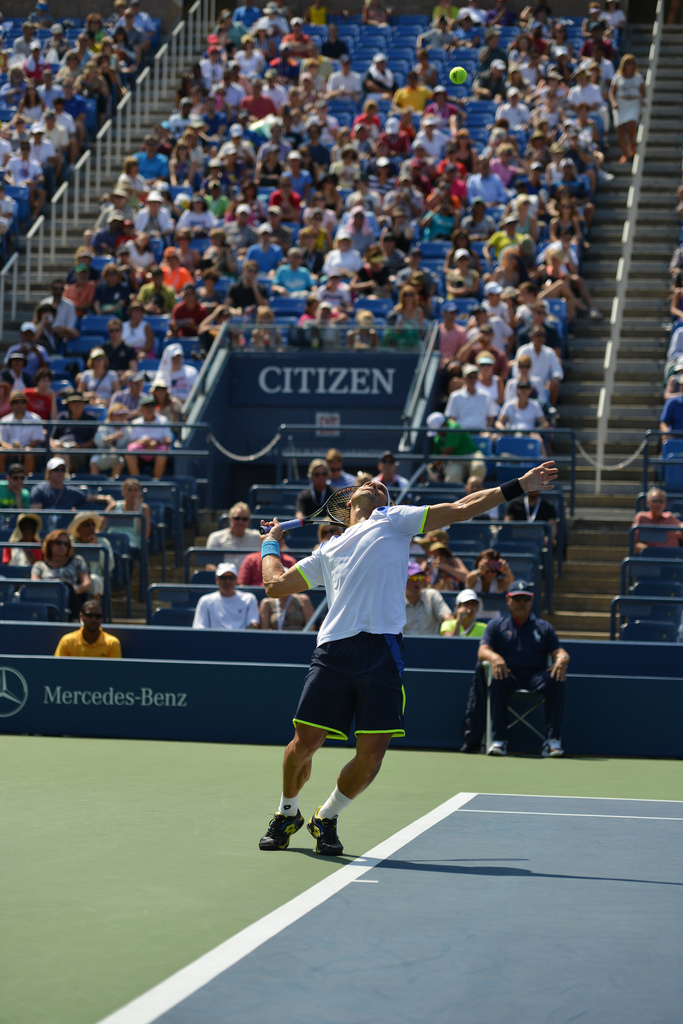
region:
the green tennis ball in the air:
[447, 63, 468, 86]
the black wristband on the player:
[501, 474, 525, 502]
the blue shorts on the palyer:
[294, 631, 412, 741]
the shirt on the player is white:
[296, 504, 432, 644]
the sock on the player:
[278, 792, 300, 818]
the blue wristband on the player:
[260, 538, 282, 558]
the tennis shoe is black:
[258, 807, 304, 852]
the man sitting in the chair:
[473, 576, 573, 755]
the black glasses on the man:
[508, 592, 533, 604]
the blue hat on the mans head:
[507, 577, 535, 597]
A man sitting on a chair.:
[496, 584, 559, 750]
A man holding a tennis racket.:
[263, 473, 402, 560]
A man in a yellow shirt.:
[62, 599, 125, 664]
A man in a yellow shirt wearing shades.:
[64, 593, 118, 666]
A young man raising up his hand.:
[342, 461, 563, 557]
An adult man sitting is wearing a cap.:
[493, 579, 553, 731]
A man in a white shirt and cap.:
[203, 560, 253, 627]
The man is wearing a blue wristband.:
[257, 479, 404, 559]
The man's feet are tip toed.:
[254, 476, 417, 862]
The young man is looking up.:
[331, 472, 408, 573]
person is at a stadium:
[54, 597, 122, 656]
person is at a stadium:
[259, 588, 313, 627]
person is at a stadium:
[477, 578, 574, 758]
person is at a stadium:
[440, 588, 486, 635]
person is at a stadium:
[392, 563, 452, 637]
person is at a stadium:
[465, 551, 512, 590]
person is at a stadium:
[423, 540, 468, 592]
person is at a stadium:
[267, 495, 322, 561]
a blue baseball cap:
[508, 578, 540, 601]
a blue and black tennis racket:
[255, 486, 356, 537]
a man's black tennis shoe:
[306, 809, 343, 853]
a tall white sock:
[316, 789, 356, 818]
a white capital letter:
[257, 363, 284, 398]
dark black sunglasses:
[80, 608, 103, 619]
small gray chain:
[572, 424, 649, 471]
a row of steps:
[554, 3, 675, 524]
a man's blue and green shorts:
[291, 619, 410, 739]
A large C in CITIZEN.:
[256, 362, 280, 396]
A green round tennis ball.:
[448, 66, 467, 85]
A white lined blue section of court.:
[95, 790, 681, 1023]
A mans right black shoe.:
[259, 802, 303, 850]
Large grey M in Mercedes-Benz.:
[43, 684, 63, 705]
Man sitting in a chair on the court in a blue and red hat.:
[477, 579, 571, 758]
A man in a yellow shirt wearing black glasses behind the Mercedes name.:
[54, 598, 123, 661]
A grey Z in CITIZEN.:
[326, 366, 349, 394]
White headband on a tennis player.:
[366, 478, 391, 507]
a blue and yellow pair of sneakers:
[255, 810, 343, 856]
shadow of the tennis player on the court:
[288, 846, 681, 889]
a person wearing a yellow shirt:
[53, 598, 122, 657]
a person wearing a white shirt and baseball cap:
[187, 558, 258, 625]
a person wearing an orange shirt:
[159, 244, 188, 292]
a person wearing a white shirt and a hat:
[63, 508, 110, 574]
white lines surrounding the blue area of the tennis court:
[98, 789, 682, 1021]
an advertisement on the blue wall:
[0, 662, 190, 722]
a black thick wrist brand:
[498, 473, 525, 506]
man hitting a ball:
[174, 46, 585, 885]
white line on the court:
[94, 744, 459, 1022]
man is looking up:
[239, 429, 584, 647]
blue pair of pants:
[276, 610, 432, 750]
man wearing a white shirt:
[261, 485, 439, 632]